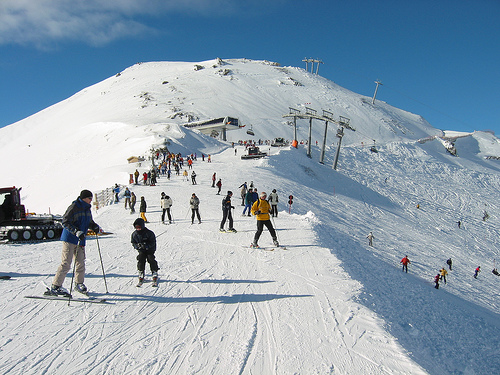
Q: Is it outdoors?
A: Yes, it is outdoors.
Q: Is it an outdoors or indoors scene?
A: It is outdoors.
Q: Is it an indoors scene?
A: No, it is outdoors.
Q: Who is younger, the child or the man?
A: The child is younger than the man.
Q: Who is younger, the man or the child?
A: The child is younger than the man.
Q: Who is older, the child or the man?
A: The man is older than the child.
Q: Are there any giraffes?
A: No, there are no giraffes.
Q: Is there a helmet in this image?
A: No, there are no helmets.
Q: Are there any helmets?
A: No, there are no helmets.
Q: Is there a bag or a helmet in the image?
A: No, there are no helmets or bags.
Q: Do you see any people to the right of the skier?
A: Yes, there is a person to the right of the skier.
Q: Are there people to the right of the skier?
A: Yes, there is a person to the right of the skier.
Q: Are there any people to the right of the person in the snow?
A: Yes, there is a person to the right of the skier.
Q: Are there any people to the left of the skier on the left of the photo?
A: No, the person is to the right of the skier.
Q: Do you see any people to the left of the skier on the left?
A: No, the person is to the right of the skier.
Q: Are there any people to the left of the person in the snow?
A: No, the person is to the right of the skier.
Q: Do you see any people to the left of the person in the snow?
A: No, the person is to the right of the skier.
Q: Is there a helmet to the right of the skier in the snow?
A: No, there is a person to the right of the skier.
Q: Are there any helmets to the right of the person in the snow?
A: No, there is a person to the right of the skier.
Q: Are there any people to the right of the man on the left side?
A: Yes, there is a person to the right of the man.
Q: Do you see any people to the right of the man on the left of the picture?
A: Yes, there is a person to the right of the man.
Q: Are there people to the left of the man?
A: No, the person is to the right of the man.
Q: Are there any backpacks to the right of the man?
A: No, there is a person to the right of the man.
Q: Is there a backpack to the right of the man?
A: No, there is a person to the right of the man.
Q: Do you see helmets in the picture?
A: No, there are no helmets.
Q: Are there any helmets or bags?
A: No, there are no helmets or bags.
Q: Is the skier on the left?
A: Yes, the skier is on the left of the image.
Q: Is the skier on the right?
A: No, the skier is on the left of the image.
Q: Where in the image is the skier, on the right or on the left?
A: The skier is on the left of the image.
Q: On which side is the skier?
A: The skier is on the left of the image.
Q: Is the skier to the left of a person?
A: Yes, the skier is to the left of a person.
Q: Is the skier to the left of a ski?
A: No, the skier is to the left of a person.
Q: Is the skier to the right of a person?
A: No, the skier is to the left of a person.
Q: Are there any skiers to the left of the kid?
A: Yes, there is a skier to the left of the kid.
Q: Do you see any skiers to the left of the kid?
A: Yes, there is a skier to the left of the kid.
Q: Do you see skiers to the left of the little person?
A: Yes, there is a skier to the left of the kid.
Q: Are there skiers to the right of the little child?
A: No, the skier is to the left of the child.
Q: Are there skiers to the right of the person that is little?
A: No, the skier is to the left of the child.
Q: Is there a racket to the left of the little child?
A: No, there is a skier to the left of the child.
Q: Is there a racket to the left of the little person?
A: No, there is a skier to the left of the child.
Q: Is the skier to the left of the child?
A: Yes, the skier is to the left of the child.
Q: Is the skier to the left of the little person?
A: Yes, the skier is to the left of the child.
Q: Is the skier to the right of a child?
A: No, the skier is to the left of a child.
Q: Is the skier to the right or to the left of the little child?
A: The skier is to the left of the child.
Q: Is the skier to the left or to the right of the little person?
A: The skier is to the left of the child.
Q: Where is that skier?
A: The skier is in the snow.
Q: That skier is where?
A: The skier is in the snow.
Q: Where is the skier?
A: The skier is in the snow.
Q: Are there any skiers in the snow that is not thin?
A: Yes, there is a skier in the snow.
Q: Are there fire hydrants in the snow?
A: No, there is a skier in the snow.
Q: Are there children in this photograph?
A: Yes, there is a child.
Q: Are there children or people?
A: Yes, there is a child.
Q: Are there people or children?
A: Yes, there is a child.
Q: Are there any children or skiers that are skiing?
A: Yes, the child is skiing.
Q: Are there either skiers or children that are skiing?
A: Yes, the child is skiing.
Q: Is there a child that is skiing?
A: Yes, there is a child that is skiing.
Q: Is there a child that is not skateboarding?
A: Yes, there is a child that is skiing.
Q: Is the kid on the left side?
A: Yes, the kid is on the left of the image.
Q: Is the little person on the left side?
A: Yes, the kid is on the left of the image.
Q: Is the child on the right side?
A: No, the child is on the left of the image.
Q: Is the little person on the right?
A: No, the child is on the left of the image.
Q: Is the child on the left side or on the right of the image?
A: The child is on the left of the image.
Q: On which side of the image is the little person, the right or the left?
A: The child is on the left of the image.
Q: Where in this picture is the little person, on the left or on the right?
A: The child is on the left of the image.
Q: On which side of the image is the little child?
A: The child is on the left of the image.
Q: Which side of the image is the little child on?
A: The child is on the left of the image.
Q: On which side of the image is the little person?
A: The child is on the left of the image.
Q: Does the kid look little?
A: Yes, the kid is little.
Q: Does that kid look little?
A: Yes, the kid is little.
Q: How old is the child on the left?
A: The child is little.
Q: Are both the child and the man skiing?
A: Yes, both the child and the man are skiing.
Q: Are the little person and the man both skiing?
A: Yes, both the child and the man are skiing.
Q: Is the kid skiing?
A: Yes, the kid is skiing.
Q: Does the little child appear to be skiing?
A: Yes, the child is skiing.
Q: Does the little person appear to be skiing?
A: Yes, the child is skiing.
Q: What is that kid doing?
A: The kid is skiing.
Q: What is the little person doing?
A: The kid is skiing.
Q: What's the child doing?
A: The kid is skiing.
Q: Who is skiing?
A: The kid is skiing.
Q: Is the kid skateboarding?
A: No, the kid is skiing.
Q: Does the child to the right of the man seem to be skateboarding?
A: No, the kid is skiing.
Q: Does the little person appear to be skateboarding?
A: No, the kid is skiing.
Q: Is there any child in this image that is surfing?
A: No, there is a child but he is skiing.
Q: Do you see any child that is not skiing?
A: No, there is a child but he is skiing.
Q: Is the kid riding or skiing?
A: The kid is skiing.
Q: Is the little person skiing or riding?
A: The kid is skiing.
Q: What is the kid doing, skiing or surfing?
A: The kid is skiing.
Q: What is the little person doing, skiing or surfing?
A: The kid is skiing.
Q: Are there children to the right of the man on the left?
A: Yes, there is a child to the right of the man.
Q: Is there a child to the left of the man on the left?
A: No, the child is to the right of the man.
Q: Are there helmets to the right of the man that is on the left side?
A: No, there is a child to the right of the man.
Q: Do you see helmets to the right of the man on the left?
A: No, there is a child to the right of the man.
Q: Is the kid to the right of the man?
A: Yes, the kid is to the right of the man.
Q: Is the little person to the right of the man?
A: Yes, the kid is to the right of the man.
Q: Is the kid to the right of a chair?
A: No, the kid is to the right of the man.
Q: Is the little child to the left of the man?
A: No, the kid is to the right of the man.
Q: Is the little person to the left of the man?
A: No, the kid is to the right of the man.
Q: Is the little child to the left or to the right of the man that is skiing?
A: The kid is to the right of the man.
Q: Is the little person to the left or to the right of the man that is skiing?
A: The kid is to the right of the man.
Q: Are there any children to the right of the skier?
A: Yes, there is a child to the right of the skier.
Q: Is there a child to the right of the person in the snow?
A: Yes, there is a child to the right of the skier.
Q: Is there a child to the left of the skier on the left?
A: No, the child is to the right of the skier.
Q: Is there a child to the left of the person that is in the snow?
A: No, the child is to the right of the skier.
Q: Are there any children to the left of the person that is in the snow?
A: No, the child is to the right of the skier.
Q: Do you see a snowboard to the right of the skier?
A: No, there is a child to the right of the skier.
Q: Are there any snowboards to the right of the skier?
A: No, there is a child to the right of the skier.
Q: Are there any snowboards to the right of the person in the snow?
A: No, there is a child to the right of the skier.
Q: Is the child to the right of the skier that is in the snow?
A: Yes, the child is to the right of the skier.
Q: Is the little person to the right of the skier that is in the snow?
A: Yes, the child is to the right of the skier.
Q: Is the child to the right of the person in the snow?
A: Yes, the child is to the right of the skier.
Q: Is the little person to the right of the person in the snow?
A: Yes, the child is to the right of the skier.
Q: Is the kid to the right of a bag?
A: No, the kid is to the right of the skier.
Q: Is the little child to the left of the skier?
A: No, the kid is to the right of the skier.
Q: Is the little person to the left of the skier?
A: No, the kid is to the right of the skier.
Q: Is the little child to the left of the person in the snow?
A: No, the kid is to the right of the skier.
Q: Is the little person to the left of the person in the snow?
A: No, the kid is to the right of the skier.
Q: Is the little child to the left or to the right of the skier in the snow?
A: The kid is to the right of the skier.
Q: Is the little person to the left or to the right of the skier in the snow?
A: The kid is to the right of the skier.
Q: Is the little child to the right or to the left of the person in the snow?
A: The kid is to the right of the skier.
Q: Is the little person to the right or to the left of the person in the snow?
A: The kid is to the right of the skier.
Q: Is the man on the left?
A: Yes, the man is on the left of the image.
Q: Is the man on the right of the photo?
A: No, the man is on the left of the image.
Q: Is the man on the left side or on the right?
A: The man is on the left of the image.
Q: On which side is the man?
A: The man is on the left of the image.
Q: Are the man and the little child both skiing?
A: Yes, both the man and the child are skiing.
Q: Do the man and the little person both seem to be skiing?
A: Yes, both the man and the child are skiing.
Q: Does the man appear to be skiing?
A: Yes, the man is skiing.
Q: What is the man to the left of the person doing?
A: The man is skiing.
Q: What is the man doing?
A: The man is skiing.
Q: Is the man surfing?
A: No, the man is skiing.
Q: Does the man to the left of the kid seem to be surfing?
A: No, the man is skiing.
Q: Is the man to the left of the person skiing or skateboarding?
A: The man is skiing.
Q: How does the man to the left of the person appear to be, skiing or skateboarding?
A: The man is skiing.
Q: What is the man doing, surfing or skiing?
A: The man is skiing.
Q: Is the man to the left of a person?
A: Yes, the man is to the left of a person.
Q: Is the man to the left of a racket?
A: No, the man is to the left of a person.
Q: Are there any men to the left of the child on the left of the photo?
A: Yes, there is a man to the left of the child.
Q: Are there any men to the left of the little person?
A: Yes, there is a man to the left of the child.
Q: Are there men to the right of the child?
A: No, the man is to the left of the child.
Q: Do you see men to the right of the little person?
A: No, the man is to the left of the child.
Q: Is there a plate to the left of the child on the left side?
A: No, there is a man to the left of the kid.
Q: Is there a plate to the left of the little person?
A: No, there is a man to the left of the kid.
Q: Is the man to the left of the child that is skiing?
A: Yes, the man is to the left of the child.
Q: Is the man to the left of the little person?
A: Yes, the man is to the left of the child.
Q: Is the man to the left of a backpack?
A: No, the man is to the left of the child.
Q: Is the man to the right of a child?
A: No, the man is to the left of a child.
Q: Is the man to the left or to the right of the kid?
A: The man is to the left of the kid.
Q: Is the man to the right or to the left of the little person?
A: The man is to the left of the kid.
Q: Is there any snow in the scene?
A: Yes, there is snow.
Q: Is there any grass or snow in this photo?
A: Yes, there is snow.